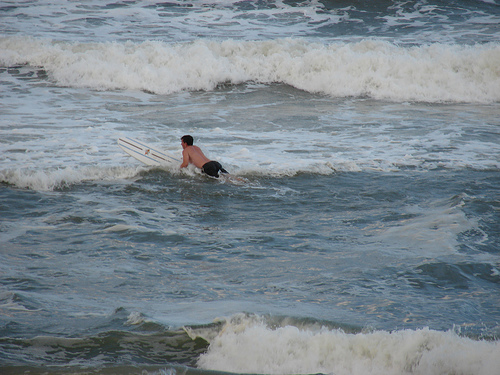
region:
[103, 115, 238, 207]
surfer paddling out into the waves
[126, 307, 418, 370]
foam and bubbles on the ocean water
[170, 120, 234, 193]
surfer is not wearing a shirt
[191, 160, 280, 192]
topless surfer in wet black shorts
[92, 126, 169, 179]
surfboard has red and blue stripes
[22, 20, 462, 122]
small foamy wave coming at the surfer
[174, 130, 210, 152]
surfer has short wet dark hair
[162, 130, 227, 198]
surfer is laying on the board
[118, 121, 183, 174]
board is half sticking out of water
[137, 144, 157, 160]
small logo printed on the white board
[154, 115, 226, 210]
surfer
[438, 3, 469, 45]
white clouds in blue sky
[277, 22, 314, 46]
white clouds in blue sky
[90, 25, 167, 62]
white clouds in blue sky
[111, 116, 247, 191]
A man surfing in the ocean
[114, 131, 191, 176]
A white surfboard beneath the man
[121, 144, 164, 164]
A small blue stripe on the surf board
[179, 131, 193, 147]
Short brown hair on the man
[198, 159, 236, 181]
A pair of black shorts on the man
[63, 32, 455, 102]
Lots of white sea foam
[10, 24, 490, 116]
A small wave behind the surfer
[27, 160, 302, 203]
A ripple of water beneath the surfer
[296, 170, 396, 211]
A patch of blue ocean water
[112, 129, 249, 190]
A man on his white surfboard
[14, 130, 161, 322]
the waves are in water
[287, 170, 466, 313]
ripples in the water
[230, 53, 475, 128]
the foam is white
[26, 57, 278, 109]
the foam is on wave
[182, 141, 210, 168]
man has no shirt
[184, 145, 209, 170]
the shirt is bare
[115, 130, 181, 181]
the board is white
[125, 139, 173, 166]
lines on the board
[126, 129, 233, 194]
man on the board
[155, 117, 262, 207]
man in the water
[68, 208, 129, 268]
a body of water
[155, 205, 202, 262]
a body of water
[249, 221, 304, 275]
a body of water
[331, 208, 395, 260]
a body of water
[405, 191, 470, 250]
a body of water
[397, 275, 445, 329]
a body of water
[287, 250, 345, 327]
a body of water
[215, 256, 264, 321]
a body of water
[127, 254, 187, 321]
a body of water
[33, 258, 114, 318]
a body of water